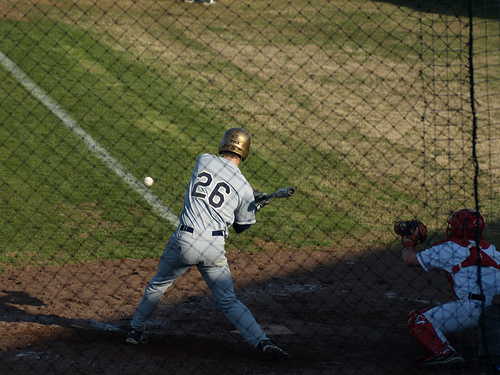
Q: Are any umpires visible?
A: No, there are no umpires.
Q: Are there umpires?
A: No, there are no umpires.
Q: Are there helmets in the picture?
A: Yes, there is a helmet.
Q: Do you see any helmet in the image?
A: Yes, there is a helmet.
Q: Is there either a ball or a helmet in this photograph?
A: Yes, there is a helmet.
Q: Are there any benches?
A: No, there are no benches.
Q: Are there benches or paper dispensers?
A: No, there are no benches or paper dispensers.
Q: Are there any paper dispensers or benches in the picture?
A: No, there are no benches or paper dispensers.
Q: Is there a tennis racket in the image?
A: No, there are no rackets.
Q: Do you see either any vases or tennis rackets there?
A: No, there are no tennis rackets or vases.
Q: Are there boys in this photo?
A: No, there are no boys.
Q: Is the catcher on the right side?
A: Yes, the catcher is on the right of the image.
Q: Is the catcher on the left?
A: No, the catcher is on the right of the image.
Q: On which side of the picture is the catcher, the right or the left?
A: The catcher is on the right of the image.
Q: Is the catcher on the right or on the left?
A: The catcher is on the right of the image.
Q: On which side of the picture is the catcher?
A: The catcher is on the right of the image.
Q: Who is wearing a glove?
A: The catcher is wearing a glove.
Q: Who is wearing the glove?
A: The catcher is wearing a glove.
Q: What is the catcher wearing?
A: The catcher is wearing a glove.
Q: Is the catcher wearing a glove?
A: Yes, the catcher is wearing a glove.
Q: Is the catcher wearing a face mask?
A: No, the catcher is wearing a glove.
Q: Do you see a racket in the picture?
A: No, there are no rackets.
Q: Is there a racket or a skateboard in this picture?
A: No, there are no rackets or skateboards.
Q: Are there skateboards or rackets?
A: No, there are no rackets or skateboards.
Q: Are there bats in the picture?
A: Yes, there is a bat.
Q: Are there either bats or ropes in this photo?
A: Yes, there is a bat.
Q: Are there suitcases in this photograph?
A: No, there are no suitcases.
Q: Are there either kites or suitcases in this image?
A: No, there are no suitcases or kites.